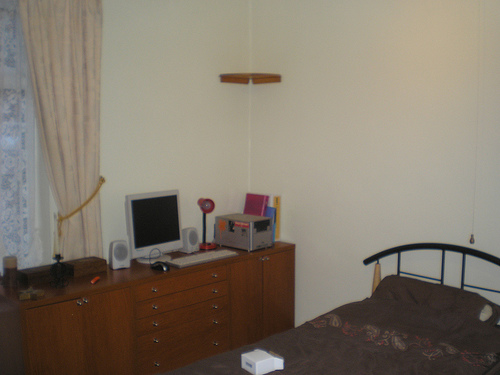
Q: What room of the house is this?
A: Bedroom.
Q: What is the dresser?
A: Beside the bed.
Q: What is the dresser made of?
A: Wood.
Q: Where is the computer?
A: On the dresser.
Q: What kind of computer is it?
A: Desktop.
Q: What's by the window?
A: Curtains.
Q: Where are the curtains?
A: By the window.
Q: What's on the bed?
A: Comforter.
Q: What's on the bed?
A: A pillow.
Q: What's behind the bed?
A: Headboard.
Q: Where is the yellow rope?
A: To the right of the window, holding back a curtain.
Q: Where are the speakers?
A: On either side of a monitor, on a dresser.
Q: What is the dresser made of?
A: Wood.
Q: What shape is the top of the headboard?
A: It is curved like a bowstring.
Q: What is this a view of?
A: A bedroom.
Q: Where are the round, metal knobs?
A: On the drawers of the wooden dresser, fronting the window.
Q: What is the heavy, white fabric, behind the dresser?
A: A curtain.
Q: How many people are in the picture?
A: None.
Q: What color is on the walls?
A: White.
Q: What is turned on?
A: Light.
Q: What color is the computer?
A: White.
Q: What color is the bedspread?
A: Brown.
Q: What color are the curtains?
A: Peach.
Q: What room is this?
A: Bedroom.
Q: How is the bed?
A: Made.